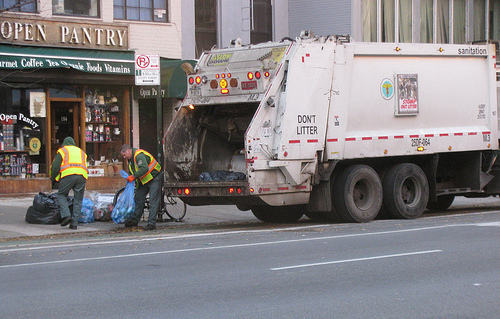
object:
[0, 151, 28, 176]
sale items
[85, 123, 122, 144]
sale items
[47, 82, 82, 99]
store window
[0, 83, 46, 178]
store window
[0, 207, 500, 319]
street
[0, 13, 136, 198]
coffee shop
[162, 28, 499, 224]
whiite truck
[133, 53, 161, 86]
sign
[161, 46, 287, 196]
garbage compactor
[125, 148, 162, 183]
vest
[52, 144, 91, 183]
vest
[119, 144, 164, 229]
man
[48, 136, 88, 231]
man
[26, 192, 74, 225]
garbage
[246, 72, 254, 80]
lights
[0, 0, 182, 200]
building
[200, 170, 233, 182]
garbage